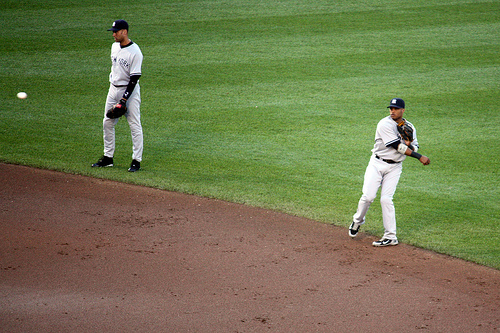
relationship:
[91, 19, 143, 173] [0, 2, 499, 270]
man on grass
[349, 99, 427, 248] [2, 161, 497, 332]
man on dirt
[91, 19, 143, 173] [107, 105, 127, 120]
man wearing glove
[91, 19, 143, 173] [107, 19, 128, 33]
man wearing cap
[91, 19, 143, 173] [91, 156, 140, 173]
man has shoes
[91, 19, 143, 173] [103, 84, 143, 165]
man wears pants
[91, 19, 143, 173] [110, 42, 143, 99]
man wears shirt